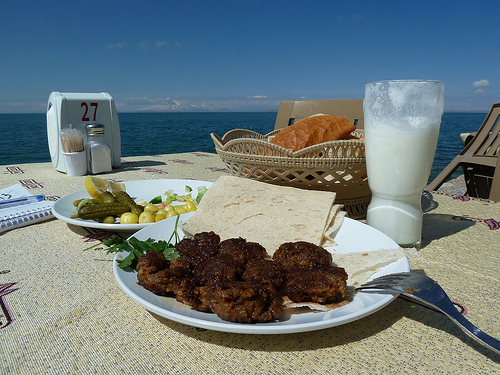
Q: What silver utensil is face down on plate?
A: Fork.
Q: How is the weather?
A: Clear with few clouds.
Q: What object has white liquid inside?
A: Ornamental glass.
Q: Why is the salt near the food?
A: For seasoning food.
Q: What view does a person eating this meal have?
A: View of water.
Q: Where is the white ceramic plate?
A: Under the food.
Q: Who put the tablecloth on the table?
A: Waitstaff.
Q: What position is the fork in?
A: Upside down.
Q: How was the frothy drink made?
A: Blender.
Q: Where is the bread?
A: Bread basket.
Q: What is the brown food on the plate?
A: Meat.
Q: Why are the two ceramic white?
A: Standard restaurant dinnerware.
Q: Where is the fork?
A: On a plate.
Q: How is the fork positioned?
A: Upside down.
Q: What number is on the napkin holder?
A: 27.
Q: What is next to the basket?
A: A glass.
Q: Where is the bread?
A: In the basket.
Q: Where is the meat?
A: On the plate.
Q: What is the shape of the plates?
A: Round.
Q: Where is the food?
A: On a table.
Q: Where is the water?
A: Beyond the table.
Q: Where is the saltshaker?
A: Next to the napkin holder.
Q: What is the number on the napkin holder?
A: 27.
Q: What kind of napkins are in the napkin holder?
A: Paper napkins.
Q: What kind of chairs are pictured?
A: Brown plastic chairs.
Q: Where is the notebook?
A: On the table.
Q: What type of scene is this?
A: Outdoor.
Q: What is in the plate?
A: Food.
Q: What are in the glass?
A: Milk.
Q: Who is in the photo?
A: No one.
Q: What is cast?
A: Shadow.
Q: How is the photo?
A: Clear.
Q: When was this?
A: Daytime.